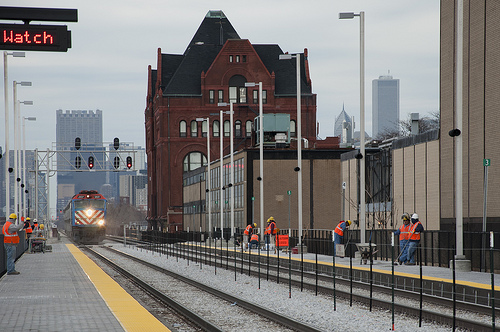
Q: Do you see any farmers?
A: No, there are no farmers.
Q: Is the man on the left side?
A: Yes, the man is on the left of the image.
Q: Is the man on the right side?
A: No, the man is on the left of the image.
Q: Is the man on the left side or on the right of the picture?
A: The man is on the left of the image.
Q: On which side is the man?
A: The man is on the left of the image.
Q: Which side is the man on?
A: The man is on the left of the image.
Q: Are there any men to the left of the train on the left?
A: Yes, there is a man to the left of the train.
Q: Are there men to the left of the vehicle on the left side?
A: Yes, there is a man to the left of the train.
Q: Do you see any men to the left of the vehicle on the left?
A: Yes, there is a man to the left of the train.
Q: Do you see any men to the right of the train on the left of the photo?
A: No, the man is to the left of the train.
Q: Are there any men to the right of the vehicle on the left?
A: No, the man is to the left of the train.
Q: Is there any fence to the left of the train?
A: No, there is a man to the left of the train.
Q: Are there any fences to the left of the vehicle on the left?
A: No, there is a man to the left of the train.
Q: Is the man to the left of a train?
A: Yes, the man is to the left of a train.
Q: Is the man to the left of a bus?
A: No, the man is to the left of a train.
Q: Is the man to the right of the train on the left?
A: No, the man is to the left of the train.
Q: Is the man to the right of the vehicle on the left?
A: No, the man is to the left of the train.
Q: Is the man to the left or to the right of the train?
A: The man is to the left of the train.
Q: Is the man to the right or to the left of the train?
A: The man is to the left of the train.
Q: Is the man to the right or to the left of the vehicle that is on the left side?
A: The man is to the left of the train.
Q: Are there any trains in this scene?
A: Yes, there is a train.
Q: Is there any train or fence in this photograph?
A: Yes, there is a train.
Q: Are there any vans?
A: No, there are no vans.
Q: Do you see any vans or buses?
A: No, there are no vans or buses.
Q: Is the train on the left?
A: Yes, the train is on the left of the image.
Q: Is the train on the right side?
A: No, the train is on the left of the image.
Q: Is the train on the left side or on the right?
A: The train is on the left of the image.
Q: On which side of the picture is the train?
A: The train is on the left of the image.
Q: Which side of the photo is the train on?
A: The train is on the left of the image.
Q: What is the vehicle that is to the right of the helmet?
A: The vehicle is a train.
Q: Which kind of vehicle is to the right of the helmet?
A: The vehicle is a train.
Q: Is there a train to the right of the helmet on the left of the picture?
A: Yes, there is a train to the right of the helmet.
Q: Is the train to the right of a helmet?
A: Yes, the train is to the right of a helmet.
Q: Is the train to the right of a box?
A: No, the train is to the right of a helmet.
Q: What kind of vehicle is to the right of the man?
A: The vehicle is a train.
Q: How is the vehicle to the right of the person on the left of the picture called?
A: The vehicle is a train.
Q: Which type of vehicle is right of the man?
A: The vehicle is a train.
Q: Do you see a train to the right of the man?
A: Yes, there is a train to the right of the man.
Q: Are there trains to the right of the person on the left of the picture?
A: Yes, there is a train to the right of the man.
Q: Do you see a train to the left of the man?
A: No, the train is to the right of the man.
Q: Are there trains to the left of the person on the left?
A: No, the train is to the right of the man.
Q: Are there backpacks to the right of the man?
A: No, there is a train to the right of the man.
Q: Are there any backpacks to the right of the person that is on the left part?
A: No, there is a train to the right of the man.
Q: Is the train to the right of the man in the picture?
A: Yes, the train is to the right of the man.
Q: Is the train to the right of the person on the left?
A: Yes, the train is to the right of the man.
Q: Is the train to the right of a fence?
A: No, the train is to the right of the man.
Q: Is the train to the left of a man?
A: No, the train is to the right of a man.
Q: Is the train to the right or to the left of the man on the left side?
A: The train is to the right of the man.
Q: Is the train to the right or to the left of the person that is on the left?
A: The train is to the right of the man.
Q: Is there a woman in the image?
A: No, there are no women.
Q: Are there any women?
A: No, there are no women.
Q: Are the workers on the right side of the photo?
A: Yes, the workers are on the right of the image.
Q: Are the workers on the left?
A: No, the workers are on the right of the image.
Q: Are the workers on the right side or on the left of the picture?
A: The workers are on the right of the image.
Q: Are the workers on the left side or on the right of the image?
A: The workers are on the right of the image.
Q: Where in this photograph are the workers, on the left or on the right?
A: The workers are on the right of the image.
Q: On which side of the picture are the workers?
A: The workers are on the right of the image.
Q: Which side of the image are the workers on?
A: The workers are on the right of the image.